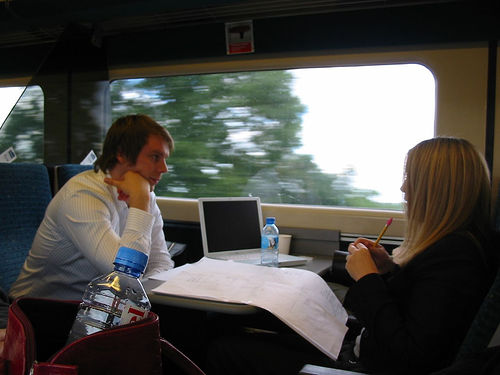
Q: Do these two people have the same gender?
A: No, they are both male and female.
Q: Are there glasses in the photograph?
A: No, there are no glasses.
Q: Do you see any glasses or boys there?
A: No, there are no glasses or boys.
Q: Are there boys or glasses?
A: No, there are no boys or glasses.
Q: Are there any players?
A: No, there are no players.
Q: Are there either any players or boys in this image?
A: No, there are no players or boys.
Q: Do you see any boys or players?
A: No, there are no players or boys.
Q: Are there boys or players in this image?
A: No, there are no players or boys.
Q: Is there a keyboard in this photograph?
A: Yes, there is a keyboard.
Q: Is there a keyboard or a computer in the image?
A: Yes, there is a keyboard.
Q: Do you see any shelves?
A: No, there are no shelves.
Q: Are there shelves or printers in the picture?
A: No, there are no shelves or printers.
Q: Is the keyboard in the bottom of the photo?
A: Yes, the keyboard is in the bottom of the image.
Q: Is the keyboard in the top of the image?
A: No, the keyboard is in the bottom of the image.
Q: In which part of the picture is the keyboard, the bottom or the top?
A: The keyboard is in the bottom of the image.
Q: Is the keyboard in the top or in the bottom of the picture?
A: The keyboard is in the bottom of the image.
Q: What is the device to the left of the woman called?
A: The device is a keyboard.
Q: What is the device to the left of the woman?
A: The device is a keyboard.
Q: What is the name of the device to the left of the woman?
A: The device is a keyboard.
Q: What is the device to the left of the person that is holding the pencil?
A: The device is a keyboard.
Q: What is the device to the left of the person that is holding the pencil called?
A: The device is a keyboard.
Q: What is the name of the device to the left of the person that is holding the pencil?
A: The device is a keyboard.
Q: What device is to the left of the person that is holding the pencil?
A: The device is a keyboard.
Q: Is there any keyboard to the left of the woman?
A: Yes, there is a keyboard to the left of the woman.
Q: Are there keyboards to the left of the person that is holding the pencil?
A: Yes, there is a keyboard to the left of the woman.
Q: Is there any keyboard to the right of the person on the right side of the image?
A: No, the keyboard is to the left of the woman.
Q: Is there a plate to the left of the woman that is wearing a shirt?
A: No, there is a keyboard to the left of the woman.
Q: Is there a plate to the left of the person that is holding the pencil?
A: No, there is a keyboard to the left of the woman.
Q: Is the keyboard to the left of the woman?
A: Yes, the keyboard is to the left of the woman.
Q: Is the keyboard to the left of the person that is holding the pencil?
A: Yes, the keyboard is to the left of the woman.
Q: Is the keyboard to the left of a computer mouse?
A: No, the keyboard is to the left of the woman.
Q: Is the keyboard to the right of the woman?
A: No, the keyboard is to the left of the woman.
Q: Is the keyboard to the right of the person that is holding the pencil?
A: No, the keyboard is to the left of the woman.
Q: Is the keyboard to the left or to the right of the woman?
A: The keyboard is to the left of the woman.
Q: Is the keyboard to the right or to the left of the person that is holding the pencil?
A: The keyboard is to the left of the woman.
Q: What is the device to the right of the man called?
A: The device is a keyboard.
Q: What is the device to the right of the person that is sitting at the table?
A: The device is a keyboard.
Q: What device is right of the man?
A: The device is a keyboard.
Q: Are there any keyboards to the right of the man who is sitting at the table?
A: Yes, there is a keyboard to the right of the man.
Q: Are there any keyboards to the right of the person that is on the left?
A: Yes, there is a keyboard to the right of the man.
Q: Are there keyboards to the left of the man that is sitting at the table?
A: No, the keyboard is to the right of the man.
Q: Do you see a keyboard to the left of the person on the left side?
A: No, the keyboard is to the right of the man.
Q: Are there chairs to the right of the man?
A: No, there is a keyboard to the right of the man.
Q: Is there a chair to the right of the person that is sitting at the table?
A: No, there is a keyboard to the right of the man.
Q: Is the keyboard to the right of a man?
A: Yes, the keyboard is to the right of a man.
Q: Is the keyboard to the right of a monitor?
A: No, the keyboard is to the right of a man.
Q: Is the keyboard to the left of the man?
A: No, the keyboard is to the right of the man.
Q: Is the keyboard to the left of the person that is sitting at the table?
A: No, the keyboard is to the right of the man.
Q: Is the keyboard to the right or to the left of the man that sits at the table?
A: The keyboard is to the right of the man.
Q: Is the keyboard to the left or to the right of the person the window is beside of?
A: The keyboard is to the right of the man.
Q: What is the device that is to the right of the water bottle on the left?
A: The device is a keyboard.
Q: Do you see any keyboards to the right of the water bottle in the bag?
A: Yes, there is a keyboard to the right of the water bottle.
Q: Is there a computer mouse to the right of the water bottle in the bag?
A: No, there is a keyboard to the right of the water bottle.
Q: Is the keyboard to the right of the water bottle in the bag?
A: Yes, the keyboard is to the right of the water bottle.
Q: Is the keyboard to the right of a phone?
A: No, the keyboard is to the right of the water bottle.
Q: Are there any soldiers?
A: No, there are no soldiers.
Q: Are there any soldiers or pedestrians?
A: No, there are no soldiers or pedestrians.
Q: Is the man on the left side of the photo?
A: Yes, the man is on the left of the image.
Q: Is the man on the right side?
A: No, the man is on the left of the image.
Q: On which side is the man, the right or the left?
A: The man is on the left of the image.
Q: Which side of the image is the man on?
A: The man is on the left of the image.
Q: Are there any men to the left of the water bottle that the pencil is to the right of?
A: Yes, there is a man to the left of the water bottle.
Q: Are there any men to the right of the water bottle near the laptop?
A: No, the man is to the left of the water bottle.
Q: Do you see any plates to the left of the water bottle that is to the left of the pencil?
A: No, there is a man to the left of the water bottle.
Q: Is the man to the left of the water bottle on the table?
A: Yes, the man is to the left of the water bottle.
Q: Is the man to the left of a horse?
A: No, the man is to the left of the water bottle.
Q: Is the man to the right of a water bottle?
A: No, the man is to the left of a water bottle.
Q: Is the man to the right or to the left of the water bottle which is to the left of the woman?
A: The man is to the left of the water bottle.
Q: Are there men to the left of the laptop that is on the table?
A: Yes, there is a man to the left of the laptop.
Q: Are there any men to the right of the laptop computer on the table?
A: No, the man is to the left of the laptop.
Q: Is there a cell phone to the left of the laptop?
A: No, there is a man to the left of the laptop.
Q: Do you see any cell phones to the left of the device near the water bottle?
A: No, there is a man to the left of the laptop.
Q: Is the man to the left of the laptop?
A: Yes, the man is to the left of the laptop.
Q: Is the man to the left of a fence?
A: No, the man is to the left of the laptop.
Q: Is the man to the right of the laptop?
A: No, the man is to the left of the laptop.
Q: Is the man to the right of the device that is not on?
A: No, the man is to the left of the laptop.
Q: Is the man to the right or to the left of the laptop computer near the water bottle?
A: The man is to the left of the laptop.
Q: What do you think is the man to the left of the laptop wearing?
A: The man is wearing a shirt.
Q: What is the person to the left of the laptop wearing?
A: The man is wearing a shirt.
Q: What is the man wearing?
A: The man is wearing a shirt.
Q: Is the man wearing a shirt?
A: Yes, the man is wearing a shirt.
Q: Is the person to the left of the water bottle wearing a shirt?
A: Yes, the man is wearing a shirt.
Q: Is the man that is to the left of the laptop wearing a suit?
A: No, the man is wearing a shirt.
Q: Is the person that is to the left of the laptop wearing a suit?
A: No, the man is wearing a shirt.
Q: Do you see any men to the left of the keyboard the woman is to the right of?
A: Yes, there is a man to the left of the keyboard.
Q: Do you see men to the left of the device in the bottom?
A: Yes, there is a man to the left of the keyboard.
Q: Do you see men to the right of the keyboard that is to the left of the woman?
A: No, the man is to the left of the keyboard.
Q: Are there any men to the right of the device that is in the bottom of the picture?
A: No, the man is to the left of the keyboard.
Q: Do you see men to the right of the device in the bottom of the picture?
A: No, the man is to the left of the keyboard.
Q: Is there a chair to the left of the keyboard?
A: No, there is a man to the left of the keyboard.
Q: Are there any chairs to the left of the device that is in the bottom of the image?
A: No, there is a man to the left of the keyboard.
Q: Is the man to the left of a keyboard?
A: Yes, the man is to the left of a keyboard.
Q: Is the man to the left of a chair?
A: No, the man is to the left of a keyboard.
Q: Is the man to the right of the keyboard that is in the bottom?
A: No, the man is to the left of the keyboard.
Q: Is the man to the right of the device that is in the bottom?
A: No, the man is to the left of the keyboard.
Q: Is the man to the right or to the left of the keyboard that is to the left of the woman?
A: The man is to the left of the keyboard.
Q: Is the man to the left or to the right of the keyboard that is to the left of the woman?
A: The man is to the left of the keyboard.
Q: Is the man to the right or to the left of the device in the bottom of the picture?
A: The man is to the left of the keyboard.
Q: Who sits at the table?
A: The man sits at the table.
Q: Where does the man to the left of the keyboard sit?
A: The man sits at the table.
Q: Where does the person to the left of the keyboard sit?
A: The man sits at the table.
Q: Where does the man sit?
A: The man sits at the table.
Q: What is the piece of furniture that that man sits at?
A: The piece of furniture is a table.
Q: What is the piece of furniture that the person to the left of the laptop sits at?
A: The piece of furniture is a table.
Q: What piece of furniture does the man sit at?
A: The man sits at the table.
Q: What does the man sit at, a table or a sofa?
A: The man sits at a table.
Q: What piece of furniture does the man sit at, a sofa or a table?
A: The man sits at a table.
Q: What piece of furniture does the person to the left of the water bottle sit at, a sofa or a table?
A: The man sits at a table.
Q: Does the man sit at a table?
A: Yes, the man sits at a table.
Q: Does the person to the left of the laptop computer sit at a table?
A: Yes, the man sits at a table.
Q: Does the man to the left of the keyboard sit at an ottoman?
A: No, the man sits at a table.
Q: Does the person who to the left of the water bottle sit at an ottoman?
A: No, the man sits at a table.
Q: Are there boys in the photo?
A: No, there are no boys.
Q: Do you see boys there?
A: No, there are no boys.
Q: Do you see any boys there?
A: No, there are no boys.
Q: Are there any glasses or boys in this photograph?
A: No, there are no boys or glasses.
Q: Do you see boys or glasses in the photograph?
A: No, there are no boys or glasses.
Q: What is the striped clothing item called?
A: The clothing item is a shirt.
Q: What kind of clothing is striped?
A: The clothing is a shirt.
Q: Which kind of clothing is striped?
A: The clothing is a shirt.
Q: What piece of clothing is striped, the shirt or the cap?
A: The shirt is striped.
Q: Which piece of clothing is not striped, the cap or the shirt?
A: The cap is not striped.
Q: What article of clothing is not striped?
A: The clothing item is a cap.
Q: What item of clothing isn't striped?
A: The clothing item is a cap.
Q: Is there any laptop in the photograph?
A: Yes, there is a laptop.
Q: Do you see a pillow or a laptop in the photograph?
A: Yes, there is a laptop.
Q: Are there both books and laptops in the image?
A: No, there is a laptop but no books.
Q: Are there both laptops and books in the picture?
A: No, there is a laptop but no books.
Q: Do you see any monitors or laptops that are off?
A: Yes, the laptop is off.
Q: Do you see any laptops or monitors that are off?
A: Yes, the laptop is off.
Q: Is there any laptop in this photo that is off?
A: Yes, there is a laptop that is off.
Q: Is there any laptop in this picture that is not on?
A: Yes, there is a laptop that is off.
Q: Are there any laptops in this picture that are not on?
A: Yes, there is a laptop that is off.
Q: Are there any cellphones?
A: No, there are no cellphones.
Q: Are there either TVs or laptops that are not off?
A: No, there is a laptop but it is off.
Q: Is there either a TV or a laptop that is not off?
A: No, there is a laptop but it is off.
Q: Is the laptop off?
A: Yes, the laptop is off.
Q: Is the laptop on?
A: No, the laptop is off.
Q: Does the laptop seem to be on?
A: No, the laptop is off.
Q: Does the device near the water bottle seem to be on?
A: No, the laptop is off.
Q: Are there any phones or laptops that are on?
A: No, there is a laptop but it is off.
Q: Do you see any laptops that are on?
A: No, there is a laptop but it is off.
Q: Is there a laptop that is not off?
A: No, there is a laptop but it is off.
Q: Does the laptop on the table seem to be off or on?
A: The laptop computer is off.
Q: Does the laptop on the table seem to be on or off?
A: The laptop computer is off.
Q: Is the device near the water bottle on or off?
A: The laptop computer is off.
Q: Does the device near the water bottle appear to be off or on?
A: The laptop computer is off.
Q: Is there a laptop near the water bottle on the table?
A: Yes, there is a laptop near the water bottle.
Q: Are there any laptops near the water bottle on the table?
A: Yes, there is a laptop near the water bottle.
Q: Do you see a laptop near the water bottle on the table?
A: Yes, there is a laptop near the water bottle.